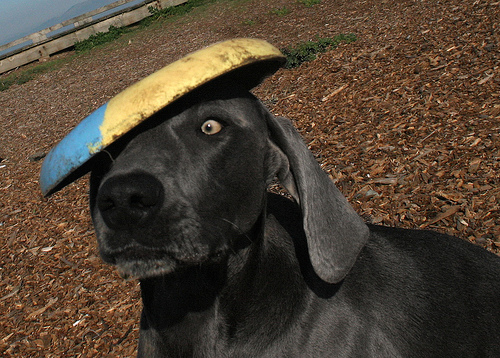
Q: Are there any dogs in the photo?
A: Yes, there is a dog.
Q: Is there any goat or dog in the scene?
A: Yes, there is a dog.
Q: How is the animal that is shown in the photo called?
A: The animal is a dog.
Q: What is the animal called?
A: The animal is a dog.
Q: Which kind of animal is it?
A: The animal is a dog.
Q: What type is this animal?
A: This is a dog.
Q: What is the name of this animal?
A: This is a dog.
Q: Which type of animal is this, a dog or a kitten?
A: This is a dog.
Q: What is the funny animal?
A: The animal is a dog.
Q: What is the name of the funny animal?
A: The animal is a dog.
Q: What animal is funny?
A: The animal is a dog.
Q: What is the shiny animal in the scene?
A: The animal is a dog.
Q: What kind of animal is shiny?
A: The animal is a dog.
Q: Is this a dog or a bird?
A: This is a dog.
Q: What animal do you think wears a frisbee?
A: The dog wears a frisbee.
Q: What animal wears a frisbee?
A: The animal is a dog.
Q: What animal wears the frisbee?
A: The animal is a dog.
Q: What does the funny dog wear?
A: The dog wears a frisbee.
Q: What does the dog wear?
A: The dog wears a frisbee.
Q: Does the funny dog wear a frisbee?
A: Yes, the dog wears a frisbee.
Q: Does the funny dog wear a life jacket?
A: No, the dog wears a frisbee.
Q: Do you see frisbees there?
A: Yes, there is a frisbee.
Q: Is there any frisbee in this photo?
A: Yes, there is a frisbee.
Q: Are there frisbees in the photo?
A: Yes, there is a frisbee.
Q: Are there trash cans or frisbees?
A: Yes, there is a frisbee.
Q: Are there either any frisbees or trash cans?
A: Yes, there is a frisbee.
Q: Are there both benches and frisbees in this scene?
A: No, there is a frisbee but no benches.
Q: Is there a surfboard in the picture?
A: No, there are no surfboards.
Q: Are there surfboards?
A: No, there are no surfboards.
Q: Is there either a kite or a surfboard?
A: No, there are no surfboards or kites.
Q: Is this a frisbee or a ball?
A: This is a frisbee.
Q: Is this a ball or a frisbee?
A: This is a frisbee.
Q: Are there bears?
A: No, there are no bears.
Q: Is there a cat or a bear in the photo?
A: No, there are no bears or cats.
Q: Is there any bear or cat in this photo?
A: No, there are no bears or cats.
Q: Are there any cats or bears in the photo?
A: No, there are no bears or cats.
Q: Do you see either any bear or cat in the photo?
A: No, there are no bears or cats.